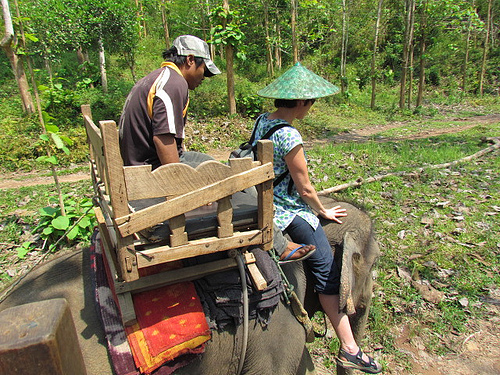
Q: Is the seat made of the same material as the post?
A: Yes, both the seat and the post are made of wood.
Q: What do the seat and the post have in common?
A: The material, both the seat and the post are wooden.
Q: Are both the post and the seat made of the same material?
A: Yes, both the post and the seat are made of wood.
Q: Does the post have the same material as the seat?
A: Yes, both the post and the seat are made of wood.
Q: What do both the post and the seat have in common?
A: The material, both the post and the seat are wooden.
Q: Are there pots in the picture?
A: No, there are no pots.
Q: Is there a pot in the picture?
A: No, there are no pots.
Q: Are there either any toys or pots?
A: No, there are no pots or toys.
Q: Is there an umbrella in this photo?
A: No, there are no umbrellas.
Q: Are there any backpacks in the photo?
A: Yes, there is a backpack.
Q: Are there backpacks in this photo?
A: Yes, there is a backpack.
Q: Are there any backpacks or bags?
A: Yes, there is a backpack.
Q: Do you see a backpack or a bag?
A: Yes, there is a backpack.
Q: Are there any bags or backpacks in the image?
A: Yes, there is a backpack.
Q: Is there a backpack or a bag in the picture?
A: Yes, there is a backpack.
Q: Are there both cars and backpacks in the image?
A: No, there is a backpack but no cars.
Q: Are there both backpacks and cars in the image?
A: No, there is a backpack but no cars.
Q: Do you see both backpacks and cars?
A: No, there is a backpack but no cars.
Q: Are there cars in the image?
A: No, there are no cars.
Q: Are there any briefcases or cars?
A: No, there are no cars or briefcases.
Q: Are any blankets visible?
A: Yes, there is a blanket.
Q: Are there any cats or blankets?
A: Yes, there is a blanket.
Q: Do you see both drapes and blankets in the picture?
A: No, there is a blanket but no drapes.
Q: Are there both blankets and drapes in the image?
A: No, there is a blanket but no drapes.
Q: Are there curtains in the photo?
A: No, there are no curtains.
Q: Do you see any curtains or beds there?
A: No, there are no curtains or beds.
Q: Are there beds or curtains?
A: No, there are no curtains or beds.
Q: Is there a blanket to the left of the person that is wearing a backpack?
A: Yes, there is a blanket to the left of the person.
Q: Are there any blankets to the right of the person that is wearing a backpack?
A: No, the blanket is to the left of the person.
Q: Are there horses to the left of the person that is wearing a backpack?
A: No, there is a blanket to the left of the person.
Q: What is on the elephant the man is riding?
A: The blanket is on the elephant.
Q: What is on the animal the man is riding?
A: The blanket is on the elephant.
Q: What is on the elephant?
A: The blanket is on the elephant.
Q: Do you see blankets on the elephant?
A: Yes, there is a blanket on the elephant.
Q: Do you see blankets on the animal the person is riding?
A: Yes, there is a blanket on the elephant.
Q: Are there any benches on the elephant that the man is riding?
A: No, there is a blanket on the elephant.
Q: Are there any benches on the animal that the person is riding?
A: No, there is a blanket on the elephant.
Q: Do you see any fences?
A: No, there are no fences.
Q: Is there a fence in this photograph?
A: No, there are no fences.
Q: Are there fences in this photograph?
A: No, there are no fences.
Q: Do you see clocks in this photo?
A: No, there are no clocks.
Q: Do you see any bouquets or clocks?
A: No, there are no clocks or bouquets.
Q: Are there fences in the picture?
A: No, there are no fences.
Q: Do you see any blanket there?
A: Yes, there is a blanket.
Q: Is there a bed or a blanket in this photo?
A: Yes, there is a blanket.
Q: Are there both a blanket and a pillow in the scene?
A: No, there is a blanket but no pillows.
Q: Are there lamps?
A: No, there are no lamps.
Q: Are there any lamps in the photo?
A: No, there are no lamps.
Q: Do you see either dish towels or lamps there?
A: No, there are no lamps or dish towels.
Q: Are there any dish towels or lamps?
A: No, there are no lamps or dish towels.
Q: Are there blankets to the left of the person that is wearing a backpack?
A: Yes, there is a blanket to the left of the person.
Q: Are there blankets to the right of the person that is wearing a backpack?
A: No, the blanket is to the left of the person.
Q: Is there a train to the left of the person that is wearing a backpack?
A: No, there is a blanket to the left of the person.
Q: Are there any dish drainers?
A: No, there are no dish drainers.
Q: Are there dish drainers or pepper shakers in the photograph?
A: No, there are no dish drainers or pepper shakers.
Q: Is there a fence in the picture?
A: No, there are no fences.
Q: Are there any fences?
A: No, there are no fences.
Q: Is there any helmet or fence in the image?
A: No, there are no fences or helmets.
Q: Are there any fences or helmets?
A: No, there are no fences or helmets.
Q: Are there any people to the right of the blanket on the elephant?
A: Yes, there is a person to the right of the blanket.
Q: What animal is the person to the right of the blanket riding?
A: The person is riding an elephant.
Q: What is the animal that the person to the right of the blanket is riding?
A: The animal is an elephant.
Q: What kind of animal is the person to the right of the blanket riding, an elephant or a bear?
A: The person is riding an elephant.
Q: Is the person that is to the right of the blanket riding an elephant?
A: Yes, the person is riding an elephant.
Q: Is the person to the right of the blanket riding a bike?
A: No, the person is riding an elephant.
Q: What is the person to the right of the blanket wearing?
A: The person is wearing a backpack.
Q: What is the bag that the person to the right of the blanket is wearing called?
A: The bag is a backpack.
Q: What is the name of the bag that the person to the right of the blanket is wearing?
A: The bag is a backpack.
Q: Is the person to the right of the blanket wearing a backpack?
A: Yes, the person is wearing a backpack.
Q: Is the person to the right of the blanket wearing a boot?
A: No, the person is wearing a backpack.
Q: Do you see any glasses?
A: No, there are no glasses.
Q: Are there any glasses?
A: No, there are no glasses.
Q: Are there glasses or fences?
A: No, there are no glasses or fences.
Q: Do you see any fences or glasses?
A: No, there are no glasses or fences.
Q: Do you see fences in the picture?
A: No, there are no fences.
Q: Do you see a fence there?
A: No, there are no fences.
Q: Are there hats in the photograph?
A: Yes, there is a hat.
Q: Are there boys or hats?
A: Yes, there is a hat.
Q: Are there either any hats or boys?
A: Yes, there is a hat.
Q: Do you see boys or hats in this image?
A: Yes, there is a hat.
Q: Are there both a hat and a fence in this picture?
A: No, there is a hat but no fences.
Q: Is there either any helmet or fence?
A: No, there are no helmets or fences.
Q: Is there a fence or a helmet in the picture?
A: No, there are no helmets or fences.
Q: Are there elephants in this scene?
A: Yes, there is an elephant.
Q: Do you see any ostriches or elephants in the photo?
A: Yes, there is an elephant.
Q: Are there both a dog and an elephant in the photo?
A: No, there is an elephant but no dogs.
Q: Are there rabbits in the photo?
A: No, there are no rabbits.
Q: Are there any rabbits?
A: No, there are no rabbits.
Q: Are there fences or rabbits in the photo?
A: No, there are no rabbits or fences.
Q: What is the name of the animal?
A: The animal is an elephant.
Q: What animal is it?
A: The animal is an elephant.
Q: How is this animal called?
A: This is an elephant.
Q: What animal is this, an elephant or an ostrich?
A: This is an elephant.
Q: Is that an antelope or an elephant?
A: That is an elephant.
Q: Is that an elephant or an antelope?
A: That is an elephant.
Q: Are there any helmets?
A: No, there are no helmets.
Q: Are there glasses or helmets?
A: No, there are no helmets or glasses.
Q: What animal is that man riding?
A: The man is riding an elephant.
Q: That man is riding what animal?
A: The man is riding an elephant.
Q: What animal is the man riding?
A: The man is riding an elephant.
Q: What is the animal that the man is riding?
A: The animal is an elephant.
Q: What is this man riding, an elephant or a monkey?
A: The man is riding an elephant.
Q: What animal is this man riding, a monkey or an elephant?
A: The man is riding an elephant.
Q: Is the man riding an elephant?
A: Yes, the man is riding an elephant.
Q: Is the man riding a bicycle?
A: No, the man is riding an elephant.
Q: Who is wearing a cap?
A: The man is wearing a cap.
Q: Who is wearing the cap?
A: The man is wearing a cap.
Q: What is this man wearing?
A: The man is wearing a cap.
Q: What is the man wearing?
A: The man is wearing a cap.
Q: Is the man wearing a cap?
A: Yes, the man is wearing a cap.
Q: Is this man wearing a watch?
A: No, the man is wearing a cap.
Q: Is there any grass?
A: Yes, there is grass.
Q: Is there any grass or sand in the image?
A: Yes, there is grass.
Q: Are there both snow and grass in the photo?
A: No, there is grass but no snow.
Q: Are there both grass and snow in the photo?
A: No, there is grass but no snow.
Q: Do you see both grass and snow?
A: No, there is grass but no snow.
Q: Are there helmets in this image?
A: No, there are no helmets.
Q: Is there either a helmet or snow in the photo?
A: No, there are no helmets or snow.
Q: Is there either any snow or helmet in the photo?
A: No, there are no helmets or snow.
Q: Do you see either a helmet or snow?
A: No, there are no helmets or snow.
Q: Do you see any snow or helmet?
A: No, there are no helmets or snow.